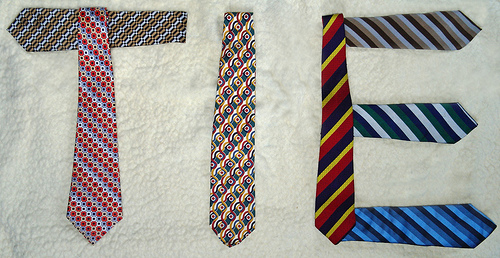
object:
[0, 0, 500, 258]
blanket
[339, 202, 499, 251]
tie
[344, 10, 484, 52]
tie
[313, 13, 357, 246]
tie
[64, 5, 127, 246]
tie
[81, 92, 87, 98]
dots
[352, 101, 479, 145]
tie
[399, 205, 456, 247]
stripes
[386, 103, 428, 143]
stripes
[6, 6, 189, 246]
sign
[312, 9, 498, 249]
letter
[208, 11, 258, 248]
letter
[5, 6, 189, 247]
letter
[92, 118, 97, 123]
circles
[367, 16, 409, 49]
strips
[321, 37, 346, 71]
strips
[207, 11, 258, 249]
tie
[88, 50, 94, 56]
polkadot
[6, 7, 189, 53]
tie